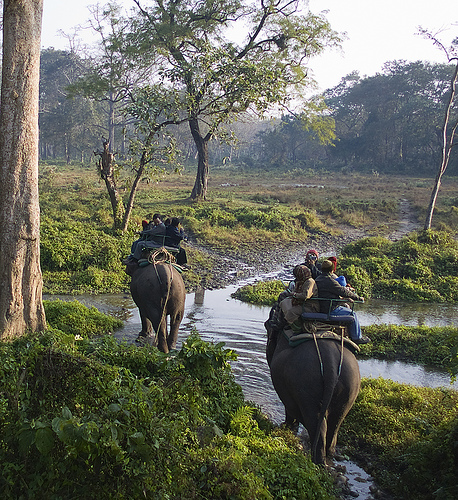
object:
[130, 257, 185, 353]
elephant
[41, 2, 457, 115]
sky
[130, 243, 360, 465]
elephants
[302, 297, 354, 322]
basket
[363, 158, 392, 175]
ground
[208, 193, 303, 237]
grass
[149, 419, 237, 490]
grass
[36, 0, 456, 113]
clouds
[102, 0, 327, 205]
tree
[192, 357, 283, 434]
grass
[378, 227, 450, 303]
grass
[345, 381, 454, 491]
grass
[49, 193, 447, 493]
river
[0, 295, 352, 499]
grass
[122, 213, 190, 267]
people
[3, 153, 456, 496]
shore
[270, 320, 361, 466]
elephant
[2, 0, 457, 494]
jungle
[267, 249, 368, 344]
people